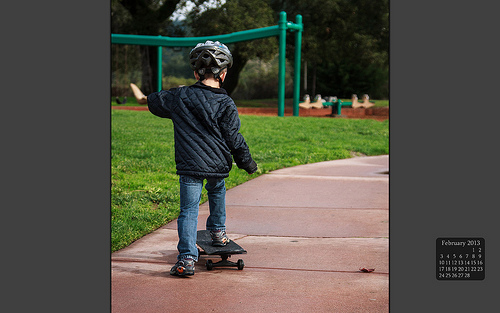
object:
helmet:
[189, 40, 234, 88]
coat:
[147, 82, 258, 177]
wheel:
[237, 259, 244, 270]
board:
[196, 230, 247, 271]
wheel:
[205, 260, 213, 271]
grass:
[269, 121, 389, 156]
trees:
[295, 0, 389, 99]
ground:
[226, 153, 394, 301]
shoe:
[170, 258, 196, 275]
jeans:
[177, 174, 225, 260]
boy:
[129, 40, 258, 276]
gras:
[299, 94, 377, 118]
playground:
[235, 91, 388, 119]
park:
[110, 2, 383, 312]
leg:
[177, 176, 203, 253]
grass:
[111, 118, 157, 201]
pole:
[277, 12, 286, 117]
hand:
[130, 83, 146, 105]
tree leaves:
[231, 9, 258, 22]